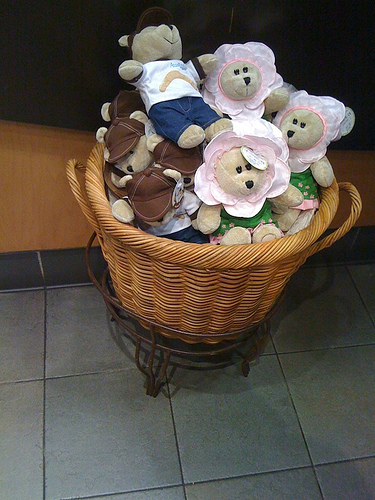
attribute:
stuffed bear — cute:
[202, 33, 285, 118]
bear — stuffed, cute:
[268, 83, 361, 234]